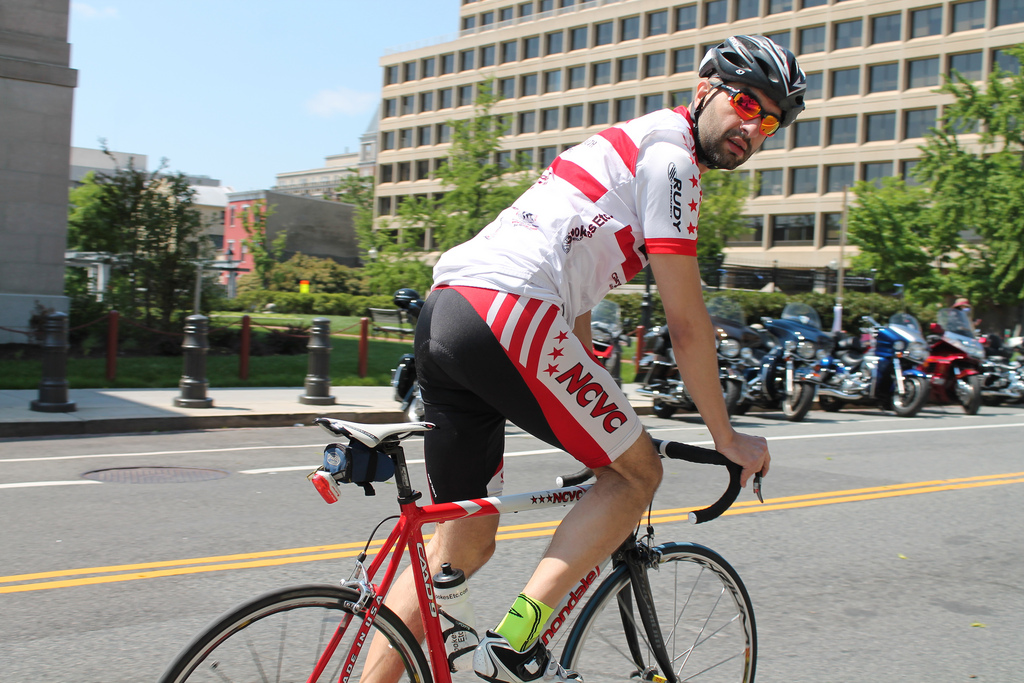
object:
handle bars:
[654, 439, 763, 524]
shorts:
[414, 284, 642, 505]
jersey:
[432, 105, 703, 331]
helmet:
[699, 35, 808, 129]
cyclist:
[351, 35, 806, 682]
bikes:
[633, 302, 1024, 421]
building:
[372, 0, 1024, 352]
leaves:
[848, 46, 1024, 306]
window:
[792, 109, 894, 149]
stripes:
[436, 285, 642, 469]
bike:
[162, 417, 757, 683]